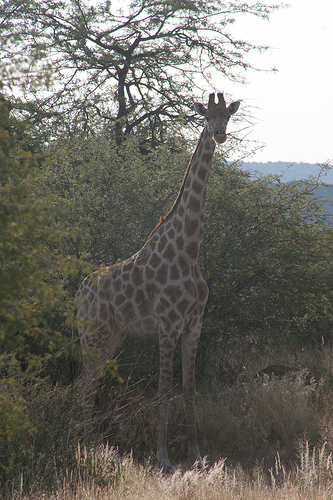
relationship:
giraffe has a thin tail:
[66, 88, 245, 478] [68, 303, 80, 355]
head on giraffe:
[192, 90, 243, 142] [66, 88, 245, 478]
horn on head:
[216, 89, 226, 106] [192, 90, 243, 142]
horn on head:
[207, 91, 214, 107] [192, 90, 243, 142]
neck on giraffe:
[156, 123, 215, 247] [66, 88, 245, 478]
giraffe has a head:
[31, 69, 255, 483] [185, 89, 247, 163]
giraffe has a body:
[66, 88, 245, 478] [52, 227, 221, 361]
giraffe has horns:
[66, 88, 245, 478] [200, 85, 232, 108]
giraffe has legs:
[66, 88, 245, 478] [144, 305, 211, 490]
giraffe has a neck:
[31, 69, 255, 483] [156, 125, 250, 248]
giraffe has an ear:
[66, 88, 245, 478] [181, 94, 219, 127]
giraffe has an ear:
[31, 69, 255, 483] [216, 91, 246, 125]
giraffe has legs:
[66, 88, 245, 478] [60, 301, 106, 478]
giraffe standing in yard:
[66, 88, 245, 478] [6, 357, 328, 495]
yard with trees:
[6, 357, 328, 495] [15, 136, 143, 242]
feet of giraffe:
[153, 444, 207, 474] [37, 90, 247, 475]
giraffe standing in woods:
[66, 88, 245, 478] [22, 96, 146, 244]